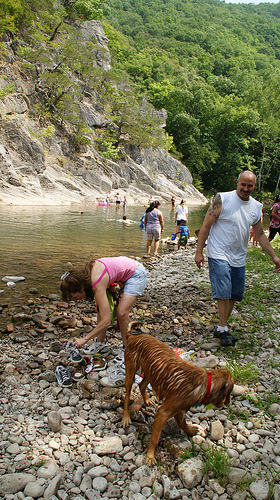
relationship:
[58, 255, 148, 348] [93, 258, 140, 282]
woman in a pink colored shirt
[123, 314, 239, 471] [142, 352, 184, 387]
dog has wet fur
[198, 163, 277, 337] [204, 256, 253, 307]
man wearing jeans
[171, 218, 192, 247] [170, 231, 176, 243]
child carrying  a bucket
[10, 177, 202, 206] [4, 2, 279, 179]
bottom of mountian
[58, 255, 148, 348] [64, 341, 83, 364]
girl bending to get shoe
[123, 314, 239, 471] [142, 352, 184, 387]
dog has wet brown fur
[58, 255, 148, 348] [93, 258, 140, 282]
lady wearing a pink shirt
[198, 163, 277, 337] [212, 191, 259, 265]
man wearing a white shirt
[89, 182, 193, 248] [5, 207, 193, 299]
people in water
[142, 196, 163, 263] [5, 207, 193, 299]
lady in water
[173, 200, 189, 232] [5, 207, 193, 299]
girl in water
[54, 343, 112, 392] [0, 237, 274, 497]
shoes on ground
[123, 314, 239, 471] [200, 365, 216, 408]
dog has a red collar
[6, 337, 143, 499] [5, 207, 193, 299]
rock at edge of water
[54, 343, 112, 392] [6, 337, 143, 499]
shoes piled on rock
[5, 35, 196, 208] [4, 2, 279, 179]
side of mountain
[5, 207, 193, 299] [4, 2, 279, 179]
water near mountain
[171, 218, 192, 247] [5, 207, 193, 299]
child near water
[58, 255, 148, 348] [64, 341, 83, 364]
woman looking for shoe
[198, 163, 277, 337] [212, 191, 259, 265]
man in a cutoff shirt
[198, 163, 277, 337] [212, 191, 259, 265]
man wearing a shirt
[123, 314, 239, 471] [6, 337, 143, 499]
dog on rock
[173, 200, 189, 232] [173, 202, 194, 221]
woman in a white shirt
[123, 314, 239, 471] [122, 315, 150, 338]
dog had a tail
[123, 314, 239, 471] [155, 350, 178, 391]
dog color brown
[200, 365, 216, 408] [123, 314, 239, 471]
collar on neck of dog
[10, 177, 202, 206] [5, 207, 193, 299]
rocks near water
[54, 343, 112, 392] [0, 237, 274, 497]
shoes on rocks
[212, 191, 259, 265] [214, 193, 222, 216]
shirt with no sleeves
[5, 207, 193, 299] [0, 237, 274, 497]
water near rocks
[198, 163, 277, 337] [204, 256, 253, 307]
man in demin shorts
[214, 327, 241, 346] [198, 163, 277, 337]
shoes are black on man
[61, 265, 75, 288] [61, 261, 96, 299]
clip in girls hair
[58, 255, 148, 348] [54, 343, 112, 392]
woman leaning over shoes